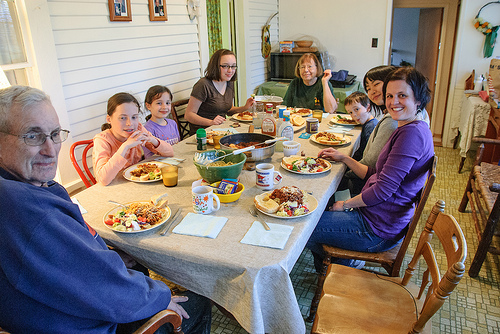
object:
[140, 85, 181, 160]
girl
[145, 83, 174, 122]
hair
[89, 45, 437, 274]
people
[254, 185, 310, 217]
dinner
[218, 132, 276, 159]
bowl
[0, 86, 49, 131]
hair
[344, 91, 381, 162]
person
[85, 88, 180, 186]
person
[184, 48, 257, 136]
person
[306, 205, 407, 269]
blue jeans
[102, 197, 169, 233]
dish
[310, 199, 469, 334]
chair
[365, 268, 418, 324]
wires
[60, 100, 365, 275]
table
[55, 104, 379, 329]
tablecloth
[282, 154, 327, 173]
food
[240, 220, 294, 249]
napkins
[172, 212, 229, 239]
napkin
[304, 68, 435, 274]
person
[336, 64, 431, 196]
person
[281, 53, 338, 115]
person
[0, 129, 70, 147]
glasses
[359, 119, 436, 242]
shirt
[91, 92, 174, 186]
person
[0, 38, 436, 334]
family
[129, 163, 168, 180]
dinner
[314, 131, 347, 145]
dinner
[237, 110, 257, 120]
dinner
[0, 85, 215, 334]
man